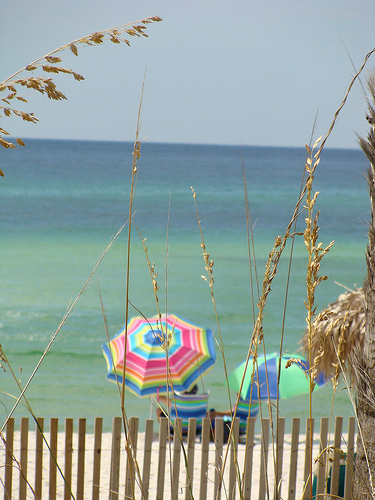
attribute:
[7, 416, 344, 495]
sandy beach — brown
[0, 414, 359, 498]
fence — slatted, wooden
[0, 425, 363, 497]
beach — sandy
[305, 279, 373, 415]
dry leaf — palm, brown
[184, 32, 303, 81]
sky — blue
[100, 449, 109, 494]
sand — brown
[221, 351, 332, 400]
striped umbrella — blue and green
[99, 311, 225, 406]
umbrellla — open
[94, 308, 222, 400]
umbrella — pink yellow green and blue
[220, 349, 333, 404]
umbrella — green and blue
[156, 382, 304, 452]
chairs — striped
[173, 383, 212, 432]
chair — striped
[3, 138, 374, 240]
water — blue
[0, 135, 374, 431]
water — large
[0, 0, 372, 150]
sky — blue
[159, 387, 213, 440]
chair — striped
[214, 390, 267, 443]
chair — striped